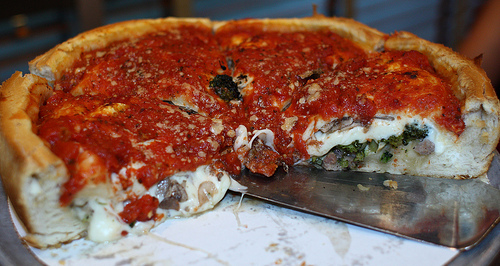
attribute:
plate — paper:
[7, 171, 498, 263]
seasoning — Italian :
[85, 50, 261, 139]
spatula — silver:
[277, 162, 499, 255]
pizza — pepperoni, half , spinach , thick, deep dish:
[10, 10, 489, 220]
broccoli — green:
[343, 145, 364, 158]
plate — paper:
[135, 230, 406, 261]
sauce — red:
[255, 37, 304, 61]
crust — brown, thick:
[1, 70, 43, 196]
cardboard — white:
[194, 219, 286, 259]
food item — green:
[210, 72, 241, 101]